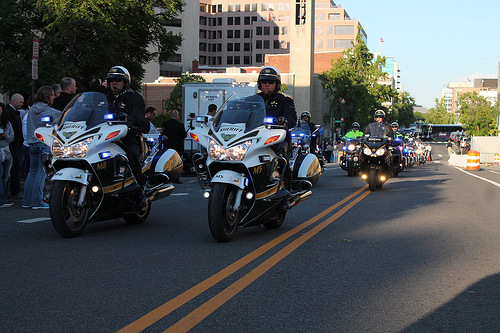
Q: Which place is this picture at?
A: It is at the street.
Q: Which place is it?
A: It is a street.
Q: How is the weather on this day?
A: It is clear.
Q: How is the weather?
A: It is clear.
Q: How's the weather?
A: It is clear.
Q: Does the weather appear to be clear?
A: Yes, it is clear.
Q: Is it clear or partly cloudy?
A: It is clear.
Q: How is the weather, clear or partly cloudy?
A: It is clear.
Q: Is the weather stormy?
A: No, it is clear.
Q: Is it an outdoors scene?
A: Yes, it is outdoors.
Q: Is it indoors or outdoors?
A: It is outdoors.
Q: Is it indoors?
A: No, it is outdoors.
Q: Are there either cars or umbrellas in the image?
A: No, there are no cars or umbrellas.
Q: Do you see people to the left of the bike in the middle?
A: Yes, there are people to the left of the bike.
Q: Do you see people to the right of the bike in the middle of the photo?
A: No, the people are to the left of the bike.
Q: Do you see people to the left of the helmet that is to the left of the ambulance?
A: Yes, there are people to the left of the helmet.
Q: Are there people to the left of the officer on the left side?
A: Yes, there are people to the left of the officer.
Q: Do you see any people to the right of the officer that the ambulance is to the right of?
A: No, the people are to the left of the officer.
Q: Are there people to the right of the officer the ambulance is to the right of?
A: No, the people are to the left of the officer.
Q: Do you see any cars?
A: No, there are no cars.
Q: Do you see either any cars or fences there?
A: No, there are no cars or fences.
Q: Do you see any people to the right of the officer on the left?
A: Yes, there is a person to the right of the officer.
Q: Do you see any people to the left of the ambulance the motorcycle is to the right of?
A: Yes, there is a person to the left of the ambulance.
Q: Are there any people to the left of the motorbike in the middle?
A: Yes, there is a person to the left of the motorcycle.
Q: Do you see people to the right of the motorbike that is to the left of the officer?
A: No, the person is to the left of the motorcycle.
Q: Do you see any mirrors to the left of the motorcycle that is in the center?
A: No, there is a person to the left of the motorbike.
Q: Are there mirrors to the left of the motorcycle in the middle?
A: No, there is a person to the left of the motorbike.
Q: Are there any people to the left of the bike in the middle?
A: Yes, there is a person to the left of the bike.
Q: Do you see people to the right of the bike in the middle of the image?
A: No, the person is to the left of the bike.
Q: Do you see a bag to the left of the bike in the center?
A: No, there is a person to the left of the bike.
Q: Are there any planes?
A: No, there are no planes.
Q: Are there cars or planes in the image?
A: No, there are no planes or cars.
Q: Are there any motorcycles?
A: Yes, there is a motorcycle.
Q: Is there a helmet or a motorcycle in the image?
A: Yes, there is a motorcycle.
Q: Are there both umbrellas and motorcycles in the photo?
A: No, there is a motorcycle but no umbrellas.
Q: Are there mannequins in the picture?
A: No, there are no mannequins.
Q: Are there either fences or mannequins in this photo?
A: No, there are no mannequins or fences.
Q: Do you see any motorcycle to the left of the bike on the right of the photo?
A: Yes, there is a motorcycle to the left of the bike.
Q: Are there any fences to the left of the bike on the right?
A: No, there is a motorcycle to the left of the bike.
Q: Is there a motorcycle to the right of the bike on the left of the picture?
A: Yes, there is a motorcycle to the right of the bike.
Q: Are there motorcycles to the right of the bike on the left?
A: Yes, there is a motorcycle to the right of the bike.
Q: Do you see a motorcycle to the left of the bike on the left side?
A: No, the motorcycle is to the right of the bike.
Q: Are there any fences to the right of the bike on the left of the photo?
A: No, there is a motorcycle to the right of the bike.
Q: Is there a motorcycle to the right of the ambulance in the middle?
A: Yes, there is a motorcycle to the right of the ambulance.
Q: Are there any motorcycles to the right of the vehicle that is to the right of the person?
A: Yes, there is a motorcycle to the right of the ambulance.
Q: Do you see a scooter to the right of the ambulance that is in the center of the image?
A: No, there is a motorcycle to the right of the ambulance.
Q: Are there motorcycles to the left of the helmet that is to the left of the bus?
A: Yes, there is a motorcycle to the left of the helmet.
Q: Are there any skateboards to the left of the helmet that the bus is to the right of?
A: No, there is a motorcycle to the left of the helmet.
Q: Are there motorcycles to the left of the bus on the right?
A: Yes, there is a motorcycle to the left of the bus.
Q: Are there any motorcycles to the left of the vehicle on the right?
A: Yes, there is a motorcycle to the left of the bus.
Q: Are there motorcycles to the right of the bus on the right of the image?
A: No, the motorcycle is to the left of the bus.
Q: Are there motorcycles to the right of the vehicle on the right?
A: No, the motorcycle is to the left of the bus.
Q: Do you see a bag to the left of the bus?
A: No, there is a motorcycle to the left of the bus.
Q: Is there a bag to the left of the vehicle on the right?
A: No, there is a motorcycle to the left of the bus.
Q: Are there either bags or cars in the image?
A: No, there are no cars or bags.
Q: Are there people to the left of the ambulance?
A: Yes, there is a person to the left of the ambulance.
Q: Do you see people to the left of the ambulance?
A: Yes, there is a person to the left of the ambulance.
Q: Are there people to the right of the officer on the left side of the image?
A: Yes, there is a person to the right of the officer.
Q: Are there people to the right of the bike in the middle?
A: No, the person is to the left of the bike.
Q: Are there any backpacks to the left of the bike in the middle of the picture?
A: No, there is a person to the left of the bike.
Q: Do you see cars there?
A: No, there are no cars.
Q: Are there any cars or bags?
A: No, there are no cars or bags.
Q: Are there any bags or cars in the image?
A: No, there are no cars or bags.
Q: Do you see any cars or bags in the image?
A: No, there are no cars or bags.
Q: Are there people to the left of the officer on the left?
A: Yes, there is a person to the left of the officer.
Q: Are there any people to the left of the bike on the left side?
A: Yes, there is a person to the left of the bike.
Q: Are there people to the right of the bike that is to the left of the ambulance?
A: No, the person is to the left of the bike.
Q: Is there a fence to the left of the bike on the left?
A: No, there is a person to the left of the bike.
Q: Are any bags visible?
A: No, there are no bags.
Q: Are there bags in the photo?
A: No, there are no bags.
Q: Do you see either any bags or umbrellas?
A: No, there are no bags or umbrellas.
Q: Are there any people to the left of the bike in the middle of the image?
A: Yes, there are people to the left of the bike.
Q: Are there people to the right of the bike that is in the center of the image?
A: No, the people are to the left of the bike.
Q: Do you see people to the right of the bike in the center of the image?
A: No, the people are to the left of the bike.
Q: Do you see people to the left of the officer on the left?
A: Yes, there are people to the left of the officer.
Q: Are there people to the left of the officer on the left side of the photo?
A: Yes, there are people to the left of the officer.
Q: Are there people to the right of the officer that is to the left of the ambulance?
A: No, the people are to the left of the officer.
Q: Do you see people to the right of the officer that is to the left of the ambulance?
A: No, the people are to the left of the officer.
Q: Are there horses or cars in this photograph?
A: No, there are no cars or horses.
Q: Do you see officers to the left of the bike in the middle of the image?
A: Yes, there is an officer to the left of the bike.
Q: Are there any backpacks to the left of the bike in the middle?
A: No, there is an officer to the left of the bike.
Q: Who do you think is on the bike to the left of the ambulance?
A: The officer is on the bike.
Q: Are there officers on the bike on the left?
A: Yes, there is an officer on the bike.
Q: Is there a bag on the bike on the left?
A: No, there is an officer on the bike.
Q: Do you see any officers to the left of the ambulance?
A: Yes, there is an officer to the left of the ambulance.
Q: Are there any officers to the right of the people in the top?
A: Yes, there is an officer to the right of the people.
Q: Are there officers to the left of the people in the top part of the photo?
A: No, the officer is to the right of the people.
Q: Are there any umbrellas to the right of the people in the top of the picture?
A: No, there is an officer to the right of the people.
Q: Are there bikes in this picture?
A: Yes, there is a bike.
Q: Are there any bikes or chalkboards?
A: Yes, there is a bike.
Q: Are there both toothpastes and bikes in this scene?
A: No, there is a bike but no toothpastes.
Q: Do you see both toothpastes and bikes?
A: No, there is a bike but no toothpastes.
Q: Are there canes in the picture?
A: No, there are no canes.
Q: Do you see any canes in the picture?
A: No, there are no canes.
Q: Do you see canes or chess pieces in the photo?
A: No, there are no canes or chess pieces.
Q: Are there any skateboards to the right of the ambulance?
A: No, there is a bike to the right of the ambulance.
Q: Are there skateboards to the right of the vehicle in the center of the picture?
A: No, there is a bike to the right of the ambulance.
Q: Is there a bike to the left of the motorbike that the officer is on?
A: Yes, there is a bike to the left of the motorcycle.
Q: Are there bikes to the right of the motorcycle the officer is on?
A: No, the bike is to the left of the motorbike.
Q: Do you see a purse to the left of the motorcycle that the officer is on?
A: No, there is a bike to the left of the motorcycle.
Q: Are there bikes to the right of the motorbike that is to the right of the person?
A: Yes, there is a bike to the right of the motorbike.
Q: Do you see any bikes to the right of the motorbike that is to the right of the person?
A: Yes, there is a bike to the right of the motorbike.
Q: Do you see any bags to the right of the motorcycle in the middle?
A: No, there is a bike to the right of the motorbike.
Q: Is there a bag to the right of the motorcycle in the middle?
A: No, there is a bike to the right of the motorbike.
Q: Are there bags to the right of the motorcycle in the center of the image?
A: No, there is a bike to the right of the motorbike.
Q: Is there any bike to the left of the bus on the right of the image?
A: Yes, there is a bike to the left of the bus.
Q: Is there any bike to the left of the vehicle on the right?
A: Yes, there is a bike to the left of the bus.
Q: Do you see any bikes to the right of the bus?
A: No, the bike is to the left of the bus.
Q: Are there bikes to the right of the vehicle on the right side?
A: No, the bike is to the left of the bus.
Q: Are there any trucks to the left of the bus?
A: No, there is a bike to the left of the bus.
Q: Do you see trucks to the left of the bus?
A: No, there is a bike to the left of the bus.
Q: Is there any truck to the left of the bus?
A: No, there is a bike to the left of the bus.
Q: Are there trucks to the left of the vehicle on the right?
A: No, there is a bike to the left of the bus.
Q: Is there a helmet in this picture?
A: Yes, there is a helmet.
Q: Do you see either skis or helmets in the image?
A: Yes, there is a helmet.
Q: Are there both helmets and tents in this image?
A: No, there is a helmet but no tents.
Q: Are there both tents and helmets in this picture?
A: No, there is a helmet but no tents.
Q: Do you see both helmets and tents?
A: No, there is a helmet but no tents.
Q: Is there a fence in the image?
A: No, there are no fences.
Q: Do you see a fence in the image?
A: No, there are no fences.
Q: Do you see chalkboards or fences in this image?
A: No, there are no fences or chalkboards.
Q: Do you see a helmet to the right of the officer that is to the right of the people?
A: Yes, there is a helmet to the right of the officer.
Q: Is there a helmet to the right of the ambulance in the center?
A: Yes, there is a helmet to the right of the ambulance.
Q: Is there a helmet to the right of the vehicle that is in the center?
A: Yes, there is a helmet to the right of the ambulance.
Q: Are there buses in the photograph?
A: Yes, there is a bus.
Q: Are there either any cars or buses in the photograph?
A: Yes, there is a bus.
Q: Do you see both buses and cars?
A: No, there is a bus but no cars.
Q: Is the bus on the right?
A: Yes, the bus is on the right of the image.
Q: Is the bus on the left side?
A: No, the bus is on the right of the image.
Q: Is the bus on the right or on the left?
A: The bus is on the right of the image.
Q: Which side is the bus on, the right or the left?
A: The bus is on the right of the image.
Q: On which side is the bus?
A: The bus is on the right of the image.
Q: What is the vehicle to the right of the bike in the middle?
A: The vehicle is a bus.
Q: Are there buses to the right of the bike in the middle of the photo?
A: Yes, there is a bus to the right of the bike.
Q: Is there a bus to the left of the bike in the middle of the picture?
A: No, the bus is to the right of the bike.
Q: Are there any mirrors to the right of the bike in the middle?
A: No, there is a bus to the right of the bike.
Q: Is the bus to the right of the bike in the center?
A: Yes, the bus is to the right of the bike.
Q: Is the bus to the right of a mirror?
A: No, the bus is to the right of the bike.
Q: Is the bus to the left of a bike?
A: No, the bus is to the right of a bike.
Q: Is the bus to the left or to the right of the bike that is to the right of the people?
A: The bus is to the right of the bike.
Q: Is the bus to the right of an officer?
A: Yes, the bus is to the right of an officer.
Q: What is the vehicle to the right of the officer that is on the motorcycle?
A: The vehicle is a bus.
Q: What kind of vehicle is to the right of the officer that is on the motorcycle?
A: The vehicle is a bus.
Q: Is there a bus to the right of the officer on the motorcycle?
A: Yes, there is a bus to the right of the officer.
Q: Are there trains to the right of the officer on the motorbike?
A: No, there is a bus to the right of the officer.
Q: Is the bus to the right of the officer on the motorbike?
A: Yes, the bus is to the right of the officer.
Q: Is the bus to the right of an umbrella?
A: No, the bus is to the right of the officer.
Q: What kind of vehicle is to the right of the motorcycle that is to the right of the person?
A: The vehicle is a bus.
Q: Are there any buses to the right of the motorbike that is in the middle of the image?
A: Yes, there is a bus to the right of the motorcycle.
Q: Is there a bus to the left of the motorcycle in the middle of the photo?
A: No, the bus is to the right of the motorcycle.